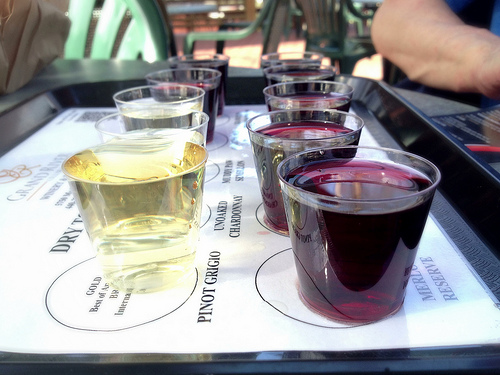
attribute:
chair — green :
[63, 2, 167, 63]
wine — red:
[298, 159, 450, 341]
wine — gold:
[62, 141, 207, 292]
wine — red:
[252, 121, 362, 231]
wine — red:
[266, 93, 352, 125]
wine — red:
[266, 70, 336, 114]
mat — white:
[0, 98, 493, 351]